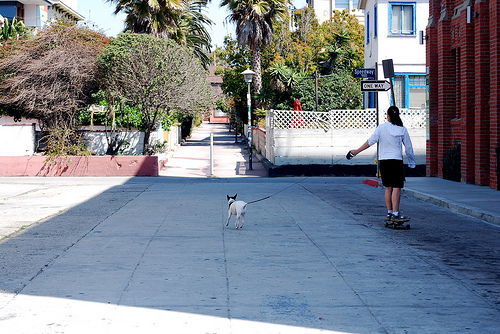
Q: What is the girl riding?
A: Skateboard.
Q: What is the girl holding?
A: Leash.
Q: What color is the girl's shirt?
A: White.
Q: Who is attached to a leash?
A: A dog.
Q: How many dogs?
A: One.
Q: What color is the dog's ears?
A: Black.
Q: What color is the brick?
A: Red.